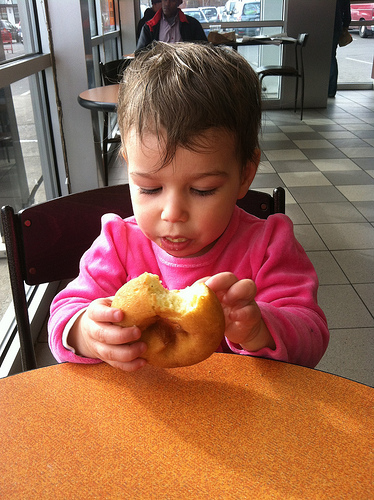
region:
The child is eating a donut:
[46, 38, 328, 369]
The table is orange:
[0, 351, 372, 498]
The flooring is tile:
[27, 86, 373, 387]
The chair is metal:
[0, 184, 286, 373]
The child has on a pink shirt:
[46, 43, 328, 368]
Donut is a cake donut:
[104, 265, 221, 371]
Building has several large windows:
[0, 0, 287, 320]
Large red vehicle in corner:
[351, 0, 372, 36]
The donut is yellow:
[109, 271, 218, 367]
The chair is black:
[2, 186, 289, 366]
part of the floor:
[309, 159, 348, 201]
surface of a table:
[199, 443, 242, 479]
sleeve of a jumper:
[266, 340, 292, 359]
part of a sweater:
[251, 239, 278, 268]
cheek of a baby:
[201, 214, 226, 241]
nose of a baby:
[168, 213, 192, 226]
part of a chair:
[45, 235, 81, 269]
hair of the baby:
[174, 92, 219, 130]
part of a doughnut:
[191, 319, 226, 345]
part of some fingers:
[226, 282, 267, 338]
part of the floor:
[336, 228, 368, 264]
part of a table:
[205, 440, 236, 467]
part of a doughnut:
[179, 334, 214, 369]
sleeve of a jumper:
[275, 321, 312, 364]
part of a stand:
[12, 318, 45, 363]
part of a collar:
[170, 244, 200, 274]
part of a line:
[333, 318, 358, 340]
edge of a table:
[315, 364, 333, 387]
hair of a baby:
[160, 114, 183, 148]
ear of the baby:
[236, 151, 262, 198]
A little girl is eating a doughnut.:
[53, 35, 346, 375]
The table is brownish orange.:
[31, 390, 307, 482]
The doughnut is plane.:
[101, 268, 224, 370]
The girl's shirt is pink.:
[84, 227, 305, 322]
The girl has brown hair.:
[114, 27, 264, 157]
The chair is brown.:
[6, 203, 116, 287]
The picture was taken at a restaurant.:
[6, 10, 343, 480]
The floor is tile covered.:
[282, 137, 373, 251]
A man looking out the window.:
[99, 1, 219, 25]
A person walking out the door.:
[325, 2, 361, 109]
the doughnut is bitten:
[103, 268, 247, 371]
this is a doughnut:
[111, 265, 221, 381]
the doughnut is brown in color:
[112, 270, 229, 368]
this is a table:
[0, 343, 363, 495]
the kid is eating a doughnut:
[63, 200, 326, 369]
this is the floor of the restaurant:
[327, 215, 367, 324]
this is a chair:
[261, 15, 316, 122]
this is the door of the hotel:
[325, 0, 370, 105]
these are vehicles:
[181, 1, 262, 36]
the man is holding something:
[328, 0, 372, 95]